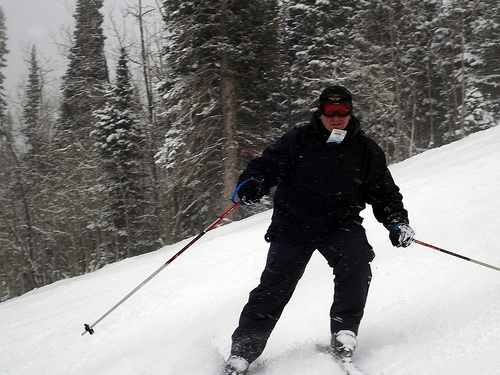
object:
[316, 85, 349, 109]
black hat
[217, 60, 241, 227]
trunk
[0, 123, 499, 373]
ground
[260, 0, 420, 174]
tree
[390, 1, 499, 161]
tree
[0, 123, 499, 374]
snow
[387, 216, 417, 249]
glove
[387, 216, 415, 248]
hand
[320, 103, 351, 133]
face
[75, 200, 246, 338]
pole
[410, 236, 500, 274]
pole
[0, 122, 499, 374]
hill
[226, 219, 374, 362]
pant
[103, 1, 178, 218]
tree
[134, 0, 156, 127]
branch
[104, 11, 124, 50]
branch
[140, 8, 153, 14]
branch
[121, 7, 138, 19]
branch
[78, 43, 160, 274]
tall tree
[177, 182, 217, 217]
branch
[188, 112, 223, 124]
branch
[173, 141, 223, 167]
branch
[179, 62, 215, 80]
branch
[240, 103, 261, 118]
branch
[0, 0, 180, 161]
sky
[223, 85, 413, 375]
man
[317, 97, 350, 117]
goggles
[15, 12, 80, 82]
sky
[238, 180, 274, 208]
glove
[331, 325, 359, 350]
snow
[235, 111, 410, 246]
black coat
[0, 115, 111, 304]
trees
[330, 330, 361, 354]
shoe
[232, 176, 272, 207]
hand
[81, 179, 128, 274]
tree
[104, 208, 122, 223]
branch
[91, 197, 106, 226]
branch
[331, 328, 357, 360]
foot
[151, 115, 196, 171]
snow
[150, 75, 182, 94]
snow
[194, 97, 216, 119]
snow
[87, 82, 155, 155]
snow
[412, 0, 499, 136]
snow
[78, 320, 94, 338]
bottom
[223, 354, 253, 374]
boot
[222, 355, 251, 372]
snow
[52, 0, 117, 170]
tall tree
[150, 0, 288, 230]
tall tree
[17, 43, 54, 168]
tall tree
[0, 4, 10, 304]
tall tree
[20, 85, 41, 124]
snow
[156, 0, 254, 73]
snow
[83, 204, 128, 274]
snow